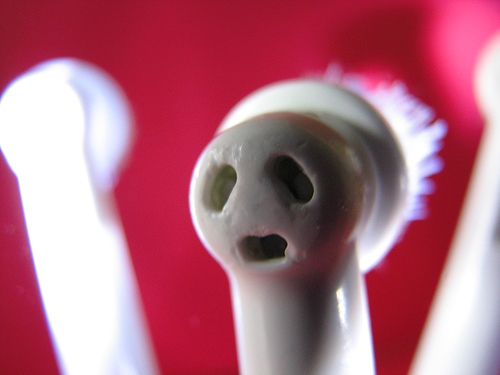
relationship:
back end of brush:
[184, 114, 376, 281] [185, 60, 448, 375]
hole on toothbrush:
[260, 148, 319, 209] [211, 77, 415, 373]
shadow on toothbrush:
[265, 270, 361, 355] [188, 62, 449, 374]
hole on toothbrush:
[200, 159, 239, 216] [188, 62, 449, 374]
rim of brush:
[219, 77, 410, 276] [175, 48, 453, 372]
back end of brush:
[184, 114, 376, 281] [175, 48, 453, 372]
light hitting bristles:
[370, 104, 431, 186] [336, 56, 446, 223]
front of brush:
[220, 78, 416, 267] [181, 60, 459, 312]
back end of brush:
[188, 116, 374, 278] [185, 60, 448, 375]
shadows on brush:
[338, 8, 465, 63] [175, 48, 453, 372]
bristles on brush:
[288, 61, 449, 272] [185, 50, 447, 346]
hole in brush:
[267, 148, 321, 204] [175, 48, 453, 372]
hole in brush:
[200, 160, 238, 216] [175, 48, 453, 372]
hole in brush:
[233, 232, 293, 265] [175, 48, 453, 372]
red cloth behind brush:
[2, 2, 499, 372] [175, 48, 453, 372]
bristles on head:
[269, 32, 474, 281] [208, 78, 410, 275]